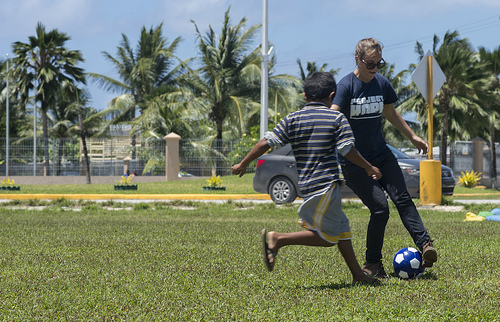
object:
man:
[330, 37, 437, 278]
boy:
[232, 71, 382, 286]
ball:
[393, 247, 426, 280]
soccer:
[6, 0, 493, 318]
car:
[253, 142, 455, 203]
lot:
[12, 132, 497, 221]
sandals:
[259, 228, 278, 273]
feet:
[260, 229, 281, 270]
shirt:
[262, 103, 357, 200]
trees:
[3, 19, 88, 176]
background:
[1, 3, 498, 179]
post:
[413, 53, 448, 206]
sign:
[409, 51, 447, 105]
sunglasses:
[358, 55, 389, 71]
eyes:
[363, 60, 376, 69]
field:
[4, 202, 500, 318]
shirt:
[329, 71, 400, 173]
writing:
[348, 93, 384, 119]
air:
[243, 214, 338, 280]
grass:
[3, 204, 500, 320]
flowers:
[456, 169, 481, 188]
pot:
[454, 186, 479, 192]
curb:
[1, 192, 499, 206]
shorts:
[296, 182, 355, 243]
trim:
[293, 189, 355, 242]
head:
[303, 71, 337, 105]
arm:
[240, 110, 296, 165]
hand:
[230, 163, 249, 178]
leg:
[279, 187, 342, 247]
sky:
[0, 1, 273, 64]